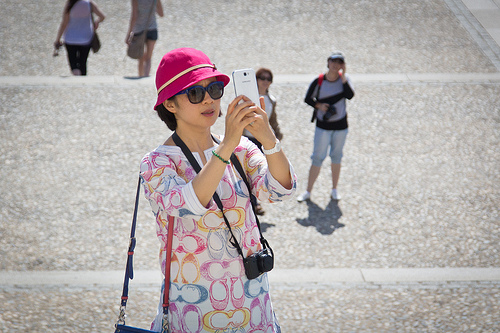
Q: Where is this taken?
A: A park.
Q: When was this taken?
A: Daytime.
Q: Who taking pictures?
A: A woman.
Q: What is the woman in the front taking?
A: A picture.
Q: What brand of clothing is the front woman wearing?
A: Coach.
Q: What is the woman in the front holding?
A: A phone.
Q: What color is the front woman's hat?
A: Pink.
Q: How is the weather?
A: Clear.